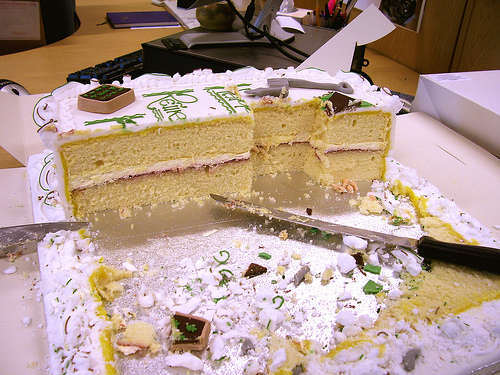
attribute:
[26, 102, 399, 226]
cake — layered, cut, green, white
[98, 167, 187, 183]
jelly — red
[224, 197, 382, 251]
blade — silver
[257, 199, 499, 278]
knife — black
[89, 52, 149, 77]
keyboard — black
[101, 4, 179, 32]
notepad — purple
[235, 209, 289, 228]
cutting edge — metallic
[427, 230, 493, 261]
handle — black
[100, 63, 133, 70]
buttons — black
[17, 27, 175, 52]
table — brown, wooden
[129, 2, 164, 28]
book — purple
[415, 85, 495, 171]
box — white, cardboard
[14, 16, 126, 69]
surface — brown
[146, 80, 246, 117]
frosting — white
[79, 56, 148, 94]
remote — black